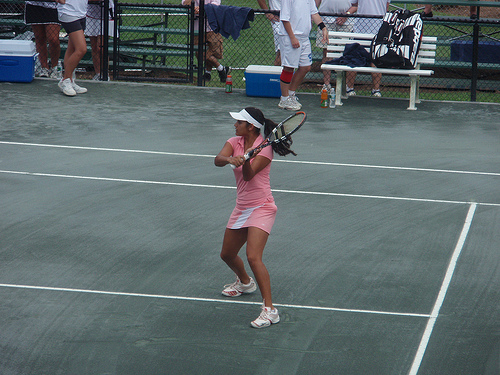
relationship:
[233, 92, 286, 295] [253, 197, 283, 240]
woman in pink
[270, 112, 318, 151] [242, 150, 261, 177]
racket being held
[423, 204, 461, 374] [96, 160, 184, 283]
line on court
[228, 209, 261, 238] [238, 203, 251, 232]
skirt has white stripe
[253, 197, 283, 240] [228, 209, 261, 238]
pink ten skirt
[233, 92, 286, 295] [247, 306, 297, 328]
woman wearing sneakers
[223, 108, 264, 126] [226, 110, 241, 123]
visor for shade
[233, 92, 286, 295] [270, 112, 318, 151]
woman with racket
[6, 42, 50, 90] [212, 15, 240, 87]
cooler by fence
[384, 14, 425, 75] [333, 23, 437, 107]
bag on bench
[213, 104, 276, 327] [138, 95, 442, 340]
woman playing tennis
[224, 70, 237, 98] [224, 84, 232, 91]
sportsdrink in bottle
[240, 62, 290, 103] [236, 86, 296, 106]
cooler on ground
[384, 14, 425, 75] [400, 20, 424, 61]
bag with stripes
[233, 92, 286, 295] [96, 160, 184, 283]
woman on court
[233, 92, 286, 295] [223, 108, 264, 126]
woman wearing visor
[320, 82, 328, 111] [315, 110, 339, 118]
drink on ground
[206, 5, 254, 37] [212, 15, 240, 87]
towel hanging on fence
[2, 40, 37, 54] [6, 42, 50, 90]
white lid on cooler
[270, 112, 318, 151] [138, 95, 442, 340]
racket for tennis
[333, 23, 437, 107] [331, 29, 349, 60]
bench with slats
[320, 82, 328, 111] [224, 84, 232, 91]
drink in bottle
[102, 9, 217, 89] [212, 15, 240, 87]
entry on fence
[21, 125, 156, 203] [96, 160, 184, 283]
lines of court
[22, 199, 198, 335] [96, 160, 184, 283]
sections of court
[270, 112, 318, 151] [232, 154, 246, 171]
racket in hands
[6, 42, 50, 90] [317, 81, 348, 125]
cooler for drinks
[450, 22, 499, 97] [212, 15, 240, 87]
black metal fence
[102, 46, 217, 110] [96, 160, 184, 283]
entry to court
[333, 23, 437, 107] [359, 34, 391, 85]
bench to sit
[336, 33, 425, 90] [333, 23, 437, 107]
bags on bench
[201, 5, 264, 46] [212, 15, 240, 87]
jacket on fence